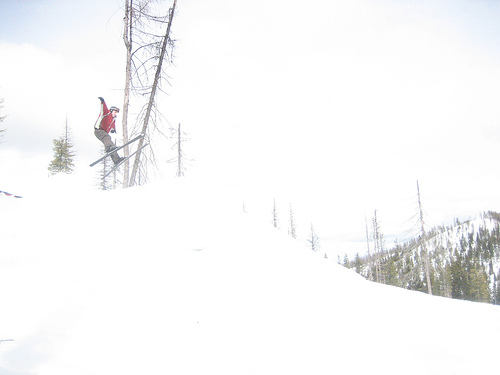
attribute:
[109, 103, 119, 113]
helmet — black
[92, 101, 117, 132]
coat — white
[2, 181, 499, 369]
hill — snowy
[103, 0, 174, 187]
trees — dead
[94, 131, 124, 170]
pants — grey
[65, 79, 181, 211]
person — balancing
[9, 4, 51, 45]
sky — blue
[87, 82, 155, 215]
skier — airborne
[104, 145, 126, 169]
boots — dark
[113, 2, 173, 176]
tree — snowy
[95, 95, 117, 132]
coat — red 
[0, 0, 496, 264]
sky — blue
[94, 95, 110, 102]
glove — black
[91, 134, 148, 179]
skies — stretched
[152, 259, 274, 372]
snow — white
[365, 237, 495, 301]
trees — distant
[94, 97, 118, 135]
coat — red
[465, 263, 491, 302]
tree — green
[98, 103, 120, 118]
helmet — black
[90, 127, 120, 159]
pant — grey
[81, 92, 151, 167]
person — jumping